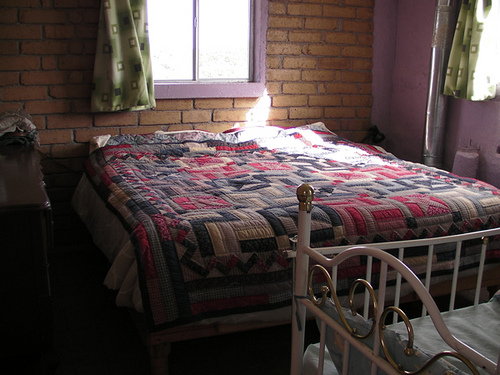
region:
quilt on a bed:
[88, 129, 499, 350]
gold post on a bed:
[291, 180, 316, 217]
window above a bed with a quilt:
[142, 0, 259, 87]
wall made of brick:
[1, 0, 376, 250]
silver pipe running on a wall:
[422, 1, 458, 167]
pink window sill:
[132, 77, 267, 102]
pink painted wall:
[370, 1, 499, 182]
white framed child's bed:
[278, 187, 499, 374]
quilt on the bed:
[98, 123, 499, 322]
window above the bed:
[118, 2, 266, 95]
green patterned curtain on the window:
[89, 1, 159, 114]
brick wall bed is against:
[4, 9, 366, 149]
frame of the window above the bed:
[147, 2, 269, 99]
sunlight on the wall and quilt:
[237, 92, 371, 167]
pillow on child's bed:
[313, 297, 458, 374]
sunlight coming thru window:
[147, 4, 249, 78]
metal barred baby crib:
[283, 180, 499, 374]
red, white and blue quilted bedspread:
[90, 120, 499, 302]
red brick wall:
[0, 0, 376, 168]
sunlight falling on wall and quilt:
[236, 86, 400, 168]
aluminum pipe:
[421, 0, 450, 167]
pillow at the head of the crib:
[317, 292, 470, 374]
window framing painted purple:
[153, 0, 268, 100]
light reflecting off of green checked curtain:
[442, 0, 497, 104]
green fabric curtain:
[81, 0, 158, 114]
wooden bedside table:
[1, 112, 63, 229]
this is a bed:
[89, 113, 496, 324]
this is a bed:
[286, 177, 499, 364]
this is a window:
[136, 0, 263, 100]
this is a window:
[443, 4, 495, 98]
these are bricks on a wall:
[286, 31, 349, 86]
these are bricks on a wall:
[324, 67, 373, 127]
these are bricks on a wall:
[15, 59, 61, 134]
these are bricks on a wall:
[179, 98, 251, 135]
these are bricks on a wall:
[269, 7, 299, 60]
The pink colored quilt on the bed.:
[87, 127, 498, 328]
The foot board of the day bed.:
[297, 179, 490, 374]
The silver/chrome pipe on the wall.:
[418, 1, 452, 167]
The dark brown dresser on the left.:
[0, 127, 62, 372]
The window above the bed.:
[143, 2, 254, 90]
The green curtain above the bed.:
[97, 2, 152, 117]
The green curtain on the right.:
[444, 1, 499, 98]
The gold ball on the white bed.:
[297, 182, 315, 211]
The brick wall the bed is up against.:
[3, 1, 378, 148]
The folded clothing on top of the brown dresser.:
[5, 108, 42, 153]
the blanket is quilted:
[134, 149, 423, 349]